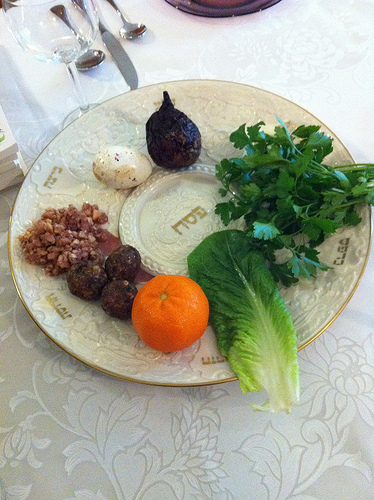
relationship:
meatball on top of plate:
[69, 259, 107, 299] [10, 76, 372, 387]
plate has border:
[10, 76, 372, 387] [7, 77, 372, 385]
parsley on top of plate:
[212, 114, 373, 288] [10, 76, 372, 387]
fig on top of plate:
[144, 90, 202, 170] [10, 76, 372, 387]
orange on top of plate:
[131, 274, 210, 355] [10, 76, 372, 387]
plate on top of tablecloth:
[10, 76, 372, 387] [1, 0, 371, 498]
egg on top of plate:
[92, 144, 152, 189] [10, 76, 372, 387]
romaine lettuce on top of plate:
[187, 228, 303, 413] [10, 76, 372, 387]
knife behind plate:
[89, 0, 139, 92] [10, 76, 372, 387]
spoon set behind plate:
[50, 3, 105, 70] [10, 76, 372, 387]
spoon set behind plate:
[106, 0, 147, 41] [10, 76, 372, 387]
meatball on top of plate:
[105, 242, 141, 281] [10, 76, 372, 387]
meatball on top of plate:
[102, 278, 138, 319] [10, 76, 372, 387]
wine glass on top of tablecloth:
[1, 1, 100, 131] [1, 0, 371, 498]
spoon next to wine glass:
[50, 3, 105, 70] [1, 1, 100, 131]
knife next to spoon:
[89, 0, 139, 92] [50, 3, 105, 70]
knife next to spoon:
[89, 0, 139, 92] [106, 0, 147, 41]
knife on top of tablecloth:
[89, 0, 139, 92] [1, 0, 371, 498]